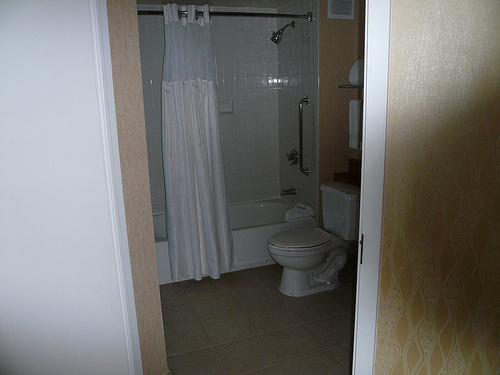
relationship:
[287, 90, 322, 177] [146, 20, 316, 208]
handle in shower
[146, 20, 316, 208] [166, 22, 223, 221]
shower has curtain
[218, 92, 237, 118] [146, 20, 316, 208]
tray in shower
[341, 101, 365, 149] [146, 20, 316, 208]
towel in shower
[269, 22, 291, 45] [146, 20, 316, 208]
head in shower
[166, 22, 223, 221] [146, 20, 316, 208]
curtain in shower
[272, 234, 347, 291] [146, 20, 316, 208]
toilet near shower